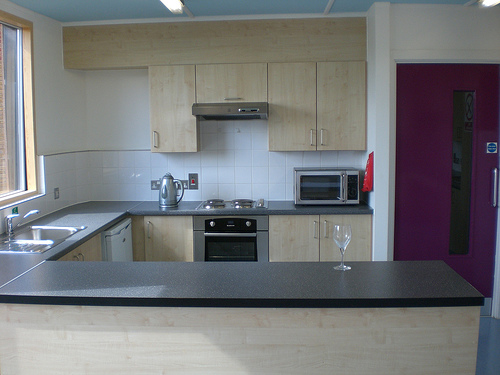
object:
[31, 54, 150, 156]
wall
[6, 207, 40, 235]
fixtures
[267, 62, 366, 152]
cabinet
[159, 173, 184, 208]
kettle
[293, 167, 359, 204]
black microwave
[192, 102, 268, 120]
hood vent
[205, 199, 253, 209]
burners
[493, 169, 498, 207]
door handle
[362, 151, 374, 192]
red mitten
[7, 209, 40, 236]
tap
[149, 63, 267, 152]
cupboard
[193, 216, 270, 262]
oven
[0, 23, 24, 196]
window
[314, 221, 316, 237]
handle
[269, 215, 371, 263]
cabinet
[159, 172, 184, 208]
pitcher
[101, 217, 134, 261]
dishwasher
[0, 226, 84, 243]
sink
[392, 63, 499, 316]
door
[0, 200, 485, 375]
counter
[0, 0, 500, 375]
kitchen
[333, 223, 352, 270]
glass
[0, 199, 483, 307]
countertop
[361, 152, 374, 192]
mitten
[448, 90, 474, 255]
window